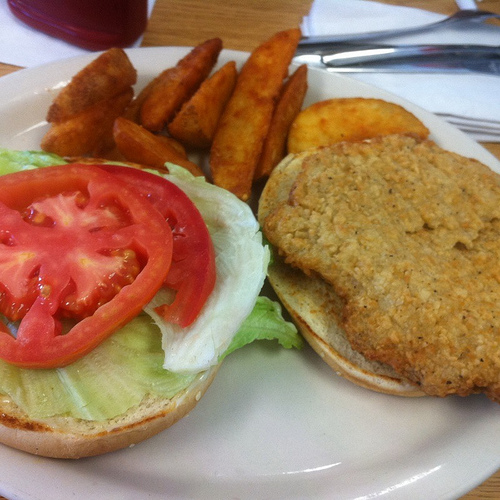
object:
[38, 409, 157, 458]
edge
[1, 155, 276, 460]
bun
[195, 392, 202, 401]
sesame seed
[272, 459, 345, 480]
reflection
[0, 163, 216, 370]
tomato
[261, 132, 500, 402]
chicken patty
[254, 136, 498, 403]
bun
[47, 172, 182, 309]
motorcycles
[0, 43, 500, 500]
plate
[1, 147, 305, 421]
lettuce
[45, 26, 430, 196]
potato wedges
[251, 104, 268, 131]
piece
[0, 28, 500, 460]
food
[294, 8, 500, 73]
fork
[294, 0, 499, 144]
napkin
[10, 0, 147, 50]
ketchup bottle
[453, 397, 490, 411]
shadow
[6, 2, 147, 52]
bottle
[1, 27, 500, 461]
lunch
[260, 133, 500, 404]
pork fritter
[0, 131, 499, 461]
sandwich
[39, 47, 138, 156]
french fry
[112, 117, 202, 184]
french fry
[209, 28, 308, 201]
french fry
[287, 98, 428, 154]
french fry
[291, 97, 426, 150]
potato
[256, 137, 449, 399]
bread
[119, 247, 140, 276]
seeds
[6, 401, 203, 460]
bun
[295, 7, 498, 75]
utensils